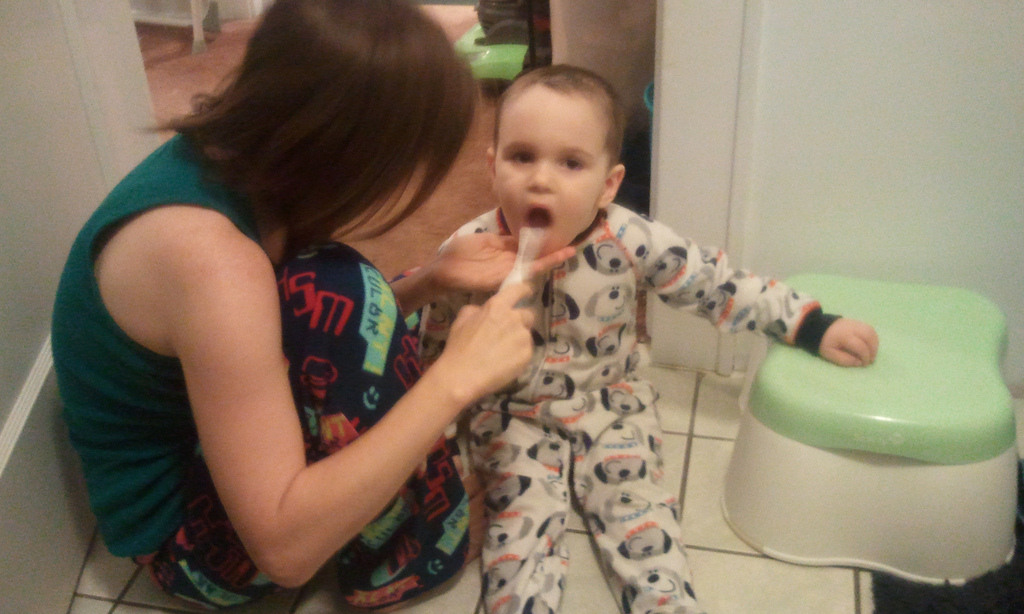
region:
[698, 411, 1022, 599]
white base of a stool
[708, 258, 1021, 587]
a child's plastic stepping stool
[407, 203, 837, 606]
pajamas on a child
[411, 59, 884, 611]
child sitting on the floor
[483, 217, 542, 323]
white toothbrush in a child's mouth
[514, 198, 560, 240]
child's open mouth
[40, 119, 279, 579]
green shirt of a woman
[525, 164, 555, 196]
nose on a child's face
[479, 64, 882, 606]
boy sitting on the floor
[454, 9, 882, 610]
little boy wearing pajamas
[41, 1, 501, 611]
girl wearing a green tank top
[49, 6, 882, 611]
girl putting something in the boys mouth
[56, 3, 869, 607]
irl and boy sitting on the bathroom floor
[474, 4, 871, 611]
boy sitting on the bathroom floor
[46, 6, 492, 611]
girl sitting on the bathroom floor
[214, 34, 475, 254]
face of the girl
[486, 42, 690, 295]
face of the boy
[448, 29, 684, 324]
face of the cute boy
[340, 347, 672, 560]
hand of the girl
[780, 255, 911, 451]
hand of the boy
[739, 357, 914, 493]
a small tub near boy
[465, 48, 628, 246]
the head of a baby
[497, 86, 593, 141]
the forhead of a baby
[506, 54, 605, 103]
the hair of a baby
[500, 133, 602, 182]
the eyes of a baby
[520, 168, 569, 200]
the nose of a baby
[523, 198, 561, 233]
the mouth of a baby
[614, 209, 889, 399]
the arm of a baby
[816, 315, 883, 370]
the hand of a baby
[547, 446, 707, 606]
the left leg of a baby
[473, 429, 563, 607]
the right leg of a baby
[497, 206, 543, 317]
Brush going into babies mouth.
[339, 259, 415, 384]
Green patch on the woman's pants.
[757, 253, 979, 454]
Green seat cover on the seat.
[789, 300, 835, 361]
Brown cuff on the baby onesie.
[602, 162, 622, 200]
Left ear of a young baby.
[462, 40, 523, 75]
Green paper in the background.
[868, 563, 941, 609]
Black carpet on top of the tile.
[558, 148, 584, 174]
Eye of a boy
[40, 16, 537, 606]
A person with long hair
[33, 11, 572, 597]
The person with long hair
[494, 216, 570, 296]
A person holding a toothbrush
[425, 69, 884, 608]
A child sitting on the floor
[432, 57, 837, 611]
The child sitting on the floor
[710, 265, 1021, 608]
A potty for a child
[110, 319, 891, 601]
The tiled floor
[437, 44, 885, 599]
the kid open his mouth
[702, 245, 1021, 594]
the potty has a green lid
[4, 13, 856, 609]
two people on the floor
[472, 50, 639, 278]
kid has short hair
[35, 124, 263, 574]
the tank is color green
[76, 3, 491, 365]
person has short hair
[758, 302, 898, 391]
a hand on a potty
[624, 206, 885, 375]
the hand is extended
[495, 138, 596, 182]
eyes are color black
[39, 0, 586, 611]
woman brushing little boys teeth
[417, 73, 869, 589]
Child in white pajamas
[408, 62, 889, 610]
Child with black hair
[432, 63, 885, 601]
Child with short hair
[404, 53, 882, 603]
Boy in white pajamas